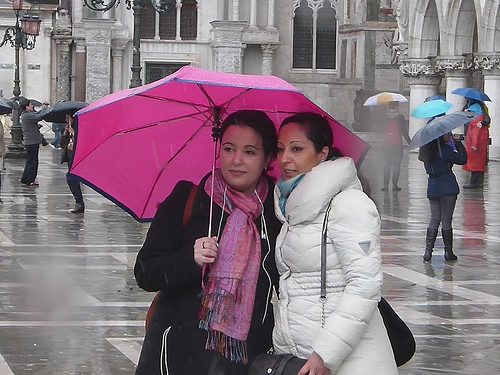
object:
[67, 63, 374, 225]
umbrella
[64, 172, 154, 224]
trim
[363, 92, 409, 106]
umbrella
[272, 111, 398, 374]
woman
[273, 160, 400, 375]
coat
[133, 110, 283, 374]
woman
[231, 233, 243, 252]
pink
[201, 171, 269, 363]
scarf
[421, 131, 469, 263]
woman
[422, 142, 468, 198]
coat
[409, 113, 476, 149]
umbrella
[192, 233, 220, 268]
hand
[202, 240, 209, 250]
ring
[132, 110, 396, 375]
women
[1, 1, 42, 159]
lamp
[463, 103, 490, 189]
person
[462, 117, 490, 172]
coat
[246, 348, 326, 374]
purse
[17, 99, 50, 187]
man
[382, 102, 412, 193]
person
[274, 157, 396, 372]
raincoat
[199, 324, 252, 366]
tassels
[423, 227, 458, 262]
boots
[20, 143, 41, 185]
pants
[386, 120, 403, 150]
backpack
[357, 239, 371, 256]
triangle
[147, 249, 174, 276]
black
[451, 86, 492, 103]
umbrella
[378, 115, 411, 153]
coat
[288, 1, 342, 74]
window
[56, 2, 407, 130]
building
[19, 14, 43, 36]
lanterns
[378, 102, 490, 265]
people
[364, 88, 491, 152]
umbrellas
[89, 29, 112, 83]
cement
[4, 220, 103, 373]
sidewalk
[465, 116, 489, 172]
raincoat